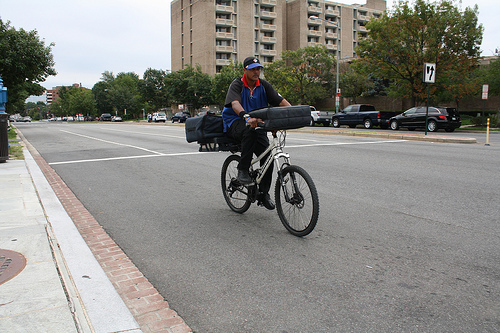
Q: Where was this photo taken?
A: On a street.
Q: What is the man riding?
A: A bicycle.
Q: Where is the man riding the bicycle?
A: In the street.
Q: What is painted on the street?
A: White lines.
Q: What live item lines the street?
A: Trees.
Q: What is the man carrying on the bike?
A: Pizzas.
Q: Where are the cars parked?
A: On the side of the street.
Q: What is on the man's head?
A: A hat.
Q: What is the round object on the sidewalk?
A: A manhole cover.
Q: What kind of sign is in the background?
A: Divided highway.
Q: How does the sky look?
A: Overcast.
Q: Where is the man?
A: In the street.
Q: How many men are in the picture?
A: One.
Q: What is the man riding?
A: Bicycle.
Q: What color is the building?
A: Brown.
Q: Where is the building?
A: In the back.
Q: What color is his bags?
A: Black.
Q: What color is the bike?
A: Silver.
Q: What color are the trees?
A: Green.